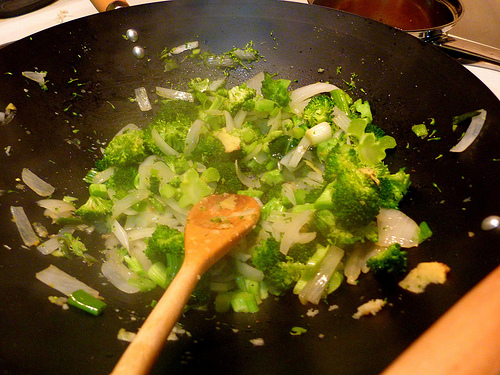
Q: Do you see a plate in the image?
A: No, there are no plates.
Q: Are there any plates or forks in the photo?
A: No, there are no plates or forks.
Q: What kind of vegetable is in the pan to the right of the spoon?
A: The vegetable is broccoli.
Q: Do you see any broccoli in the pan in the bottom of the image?
A: Yes, there is broccoli in the pan.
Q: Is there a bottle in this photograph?
A: No, there are no bottles.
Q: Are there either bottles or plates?
A: No, there are no bottles or plates.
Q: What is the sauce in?
A: The sauce is in the pan.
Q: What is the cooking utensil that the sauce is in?
A: The cooking utensil is a pan.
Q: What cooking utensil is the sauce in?
A: The sauce is in the pan.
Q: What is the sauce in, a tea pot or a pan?
A: The sauce is in a pan.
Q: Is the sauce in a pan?
A: Yes, the sauce is in a pan.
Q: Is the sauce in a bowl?
A: No, the sauce is in a pan.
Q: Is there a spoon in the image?
A: Yes, there is a spoon.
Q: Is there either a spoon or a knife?
A: Yes, there is a spoon.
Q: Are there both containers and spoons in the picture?
A: No, there is a spoon but no containers.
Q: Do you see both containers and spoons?
A: No, there is a spoon but no containers.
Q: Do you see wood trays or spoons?
A: Yes, there is a wood spoon.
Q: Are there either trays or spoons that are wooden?
A: Yes, the spoon is wooden.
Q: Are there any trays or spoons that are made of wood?
A: Yes, the spoon is made of wood.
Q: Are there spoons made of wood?
A: Yes, there is a spoon that is made of wood.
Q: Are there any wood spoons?
A: Yes, there is a spoon that is made of wood.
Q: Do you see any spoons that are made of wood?
A: Yes, there is a spoon that is made of wood.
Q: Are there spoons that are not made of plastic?
A: Yes, there is a spoon that is made of wood.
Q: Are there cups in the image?
A: No, there are no cups.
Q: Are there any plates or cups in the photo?
A: No, there are no cups or plates.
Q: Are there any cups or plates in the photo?
A: No, there are no cups or plates.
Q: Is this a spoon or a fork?
A: This is a spoon.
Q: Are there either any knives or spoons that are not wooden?
A: No, there is a spoon but it is wooden.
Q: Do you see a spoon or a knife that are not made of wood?
A: No, there is a spoon but it is made of wood.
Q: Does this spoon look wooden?
A: Yes, the spoon is wooden.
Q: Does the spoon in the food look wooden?
A: Yes, the spoon is wooden.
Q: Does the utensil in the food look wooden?
A: Yes, the spoon is wooden.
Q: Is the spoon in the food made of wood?
A: Yes, the spoon is made of wood.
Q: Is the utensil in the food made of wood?
A: Yes, the spoon is made of wood.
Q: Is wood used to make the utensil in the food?
A: Yes, the spoon is made of wood.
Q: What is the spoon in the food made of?
A: The spoon is made of wood.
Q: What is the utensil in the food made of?
A: The spoon is made of wood.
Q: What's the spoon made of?
A: The spoon is made of wood.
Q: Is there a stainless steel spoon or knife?
A: No, there is a spoon but it is wooden.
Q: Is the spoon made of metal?
A: No, the spoon is made of wood.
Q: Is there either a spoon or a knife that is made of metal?
A: No, there is a spoon but it is made of wood.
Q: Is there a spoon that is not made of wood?
A: No, there is a spoon but it is made of wood.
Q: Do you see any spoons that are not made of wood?
A: No, there is a spoon but it is made of wood.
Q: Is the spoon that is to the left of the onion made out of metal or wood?
A: The spoon is made of wood.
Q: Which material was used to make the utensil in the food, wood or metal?
A: The spoon is made of wood.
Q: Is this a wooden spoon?
A: Yes, this is a wooden spoon.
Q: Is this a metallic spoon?
A: No, this is a wooden spoon.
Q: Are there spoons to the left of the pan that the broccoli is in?
A: Yes, there is a spoon to the left of the pan.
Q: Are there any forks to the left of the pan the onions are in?
A: No, there is a spoon to the left of the pan.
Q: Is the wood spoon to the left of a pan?
A: Yes, the spoon is to the left of a pan.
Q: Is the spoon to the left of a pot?
A: No, the spoon is to the left of a pan.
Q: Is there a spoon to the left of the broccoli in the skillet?
A: Yes, there is a spoon to the left of the broccoli.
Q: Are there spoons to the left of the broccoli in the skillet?
A: Yes, there is a spoon to the left of the broccoli.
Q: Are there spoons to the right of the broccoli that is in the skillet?
A: No, the spoon is to the left of the broccoli.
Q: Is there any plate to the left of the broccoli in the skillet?
A: No, there is a spoon to the left of the broccoli.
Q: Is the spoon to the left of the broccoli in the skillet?
A: Yes, the spoon is to the left of the broccoli.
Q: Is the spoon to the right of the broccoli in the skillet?
A: No, the spoon is to the left of the broccoli.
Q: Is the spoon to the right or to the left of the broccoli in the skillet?
A: The spoon is to the left of the broccoli.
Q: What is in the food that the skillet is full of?
A: The spoon is in the food.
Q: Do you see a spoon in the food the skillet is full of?
A: Yes, there is a spoon in the food.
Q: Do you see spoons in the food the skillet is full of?
A: Yes, there is a spoon in the food.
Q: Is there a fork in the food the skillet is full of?
A: No, there is a spoon in the food.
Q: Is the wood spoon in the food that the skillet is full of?
A: Yes, the spoon is in the food.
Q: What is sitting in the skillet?
A: The spoon is sitting in the skillet.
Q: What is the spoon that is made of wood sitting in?
A: The spoon is sitting in the skillet.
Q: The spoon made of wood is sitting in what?
A: The spoon is sitting in the skillet.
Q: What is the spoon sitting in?
A: The spoon is sitting in the skillet.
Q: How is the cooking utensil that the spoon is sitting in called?
A: The cooking utensil is a skillet.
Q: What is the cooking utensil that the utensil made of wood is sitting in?
A: The cooking utensil is a skillet.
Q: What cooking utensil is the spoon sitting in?
A: The spoon is sitting in the skillet.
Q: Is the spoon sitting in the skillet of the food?
A: Yes, the spoon is sitting in the skillet.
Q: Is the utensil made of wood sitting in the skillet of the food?
A: Yes, the spoon is sitting in the skillet.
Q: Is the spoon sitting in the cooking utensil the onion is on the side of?
A: Yes, the spoon is sitting in the skillet.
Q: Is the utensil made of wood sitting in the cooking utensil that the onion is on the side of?
A: Yes, the spoon is sitting in the skillet.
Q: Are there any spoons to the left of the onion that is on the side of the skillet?
A: Yes, there is a spoon to the left of the onion.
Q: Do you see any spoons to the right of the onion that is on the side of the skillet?
A: No, the spoon is to the left of the onion.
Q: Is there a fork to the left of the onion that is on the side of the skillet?
A: No, there is a spoon to the left of the onion.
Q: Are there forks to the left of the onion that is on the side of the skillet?
A: No, there is a spoon to the left of the onion.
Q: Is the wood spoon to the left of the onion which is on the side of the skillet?
A: Yes, the spoon is to the left of the onion.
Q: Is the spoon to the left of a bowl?
A: No, the spoon is to the left of the onion.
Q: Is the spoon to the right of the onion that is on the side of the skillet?
A: No, the spoon is to the left of the onion.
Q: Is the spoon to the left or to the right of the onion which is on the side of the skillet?
A: The spoon is to the left of the onion.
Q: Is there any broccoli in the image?
A: Yes, there is broccoli.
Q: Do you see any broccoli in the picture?
A: Yes, there is broccoli.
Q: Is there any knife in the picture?
A: No, there are no knives.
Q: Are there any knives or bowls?
A: No, there are no knives or bowls.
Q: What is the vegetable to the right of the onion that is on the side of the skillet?
A: The vegetable is broccoli.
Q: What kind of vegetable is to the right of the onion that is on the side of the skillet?
A: The vegetable is broccoli.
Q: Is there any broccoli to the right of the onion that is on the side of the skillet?
A: Yes, there is broccoli to the right of the onion.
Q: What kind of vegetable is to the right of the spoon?
A: The vegetable is broccoli.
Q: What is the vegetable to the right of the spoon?
A: The vegetable is broccoli.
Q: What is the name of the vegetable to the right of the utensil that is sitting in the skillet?
A: The vegetable is broccoli.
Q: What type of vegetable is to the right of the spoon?
A: The vegetable is broccoli.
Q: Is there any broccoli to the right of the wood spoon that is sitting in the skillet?
A: Yes, there is broccoli to the right of the spoon.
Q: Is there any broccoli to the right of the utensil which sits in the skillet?
A: Yes, there is broccoli to the right of the spoon.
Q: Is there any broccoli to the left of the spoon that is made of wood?
A: No, the broccoli is to the right of the spoon.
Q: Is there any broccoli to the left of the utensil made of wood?
A: No, the broccoli is to the right of the spoon.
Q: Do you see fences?
A: No, there are no fences.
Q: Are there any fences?
A: No, there are no fences.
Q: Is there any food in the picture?
A: Yes, there is food.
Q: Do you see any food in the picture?
A: Yes, there is food.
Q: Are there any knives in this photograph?
A: No, there are no knives.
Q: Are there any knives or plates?
A: No, there are no knives or plates.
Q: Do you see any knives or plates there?
A: No, there are no knives or plates.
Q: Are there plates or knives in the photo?
A: No, there are no knives or plates.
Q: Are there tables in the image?
A: Yes, there is a table.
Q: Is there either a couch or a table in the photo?
A: Yes, there is a table.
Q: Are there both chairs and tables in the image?
A: No, there is a table but no chairs.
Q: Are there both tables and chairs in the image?
A: No, there is a table but no chairs.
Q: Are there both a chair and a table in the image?
A: No, there is a table but no chairs.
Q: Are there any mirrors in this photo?
A: No, there are no mirrors.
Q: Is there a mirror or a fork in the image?
A: No, there are no mirrors or forks.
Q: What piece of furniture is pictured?
A: The piece of furniture is a table.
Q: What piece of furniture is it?
A: The piece of furniture is a table.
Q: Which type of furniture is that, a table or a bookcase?
A: This is a table.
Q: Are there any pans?
A: Yes, there is a pan.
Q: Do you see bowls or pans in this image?
A: Yes, there is a pan.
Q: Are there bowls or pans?
A: Yes, there is a pan.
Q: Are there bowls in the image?
A: No, there are no bowls.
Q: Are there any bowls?
A: No, there are no bowls.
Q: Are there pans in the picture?
A: Yes, there is a pan.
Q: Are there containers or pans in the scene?
A: Yes, there is a pan.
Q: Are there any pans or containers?
A: Yes, there is a pan.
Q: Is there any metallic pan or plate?
A: Yes, there is a metal pan.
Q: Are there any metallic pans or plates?
A: Yes, there is a metal pan.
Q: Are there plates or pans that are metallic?
A: Yes, the pan is metallic.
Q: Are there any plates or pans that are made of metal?
A: Yes, the pan is made of metal.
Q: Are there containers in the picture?
A: No, there are no containers.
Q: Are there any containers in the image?
A: No, there are no containers.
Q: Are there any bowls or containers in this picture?
A: No, there are no containers or bowls.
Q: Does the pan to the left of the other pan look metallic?
A: Yes, the pan is metallic.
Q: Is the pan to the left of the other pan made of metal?
A: Yes, the pan is made of metal.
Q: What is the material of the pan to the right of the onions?
A: The pan is made of metal.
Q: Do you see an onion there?
A: Yes, there is an onion.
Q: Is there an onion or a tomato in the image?
A: Yes, there is an onion.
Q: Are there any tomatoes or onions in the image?
A: Yes, there is an onion.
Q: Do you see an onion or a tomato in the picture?
A: Yes, there is an onion.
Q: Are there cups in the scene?
A: No, there are no cups.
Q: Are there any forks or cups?
A: No, there are no cups or forks.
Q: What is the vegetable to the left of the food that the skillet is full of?
A: The vegetable is an onion.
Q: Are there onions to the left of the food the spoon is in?
A: Yes, there is an onion to the left of the food.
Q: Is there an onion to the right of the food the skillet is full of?
A: No, the onion is to the left of the food.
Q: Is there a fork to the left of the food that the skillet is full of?
A: No, there is an onion to the left of the food.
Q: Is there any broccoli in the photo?
A: Yes, there is broccoli.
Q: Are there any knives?
A: No, there are no knives.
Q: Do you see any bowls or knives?
A: No, there are no knives or bowls.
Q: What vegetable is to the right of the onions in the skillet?
A: The vegetable is broccoli.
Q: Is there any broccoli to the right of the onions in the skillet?
A: Yes, there is broccoli to the right of the onions.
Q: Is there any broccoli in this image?
A: Yes, there is broccoli.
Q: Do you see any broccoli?
A: Yes, there is broccoli.